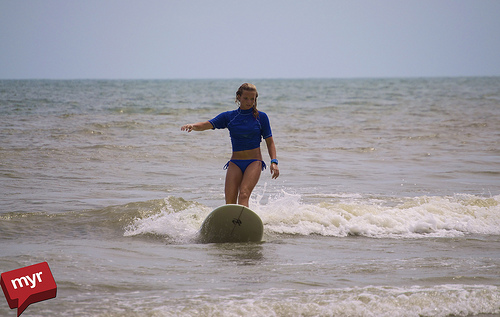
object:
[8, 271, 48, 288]
letter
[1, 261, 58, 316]
box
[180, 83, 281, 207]
surfer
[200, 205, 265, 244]
surfboard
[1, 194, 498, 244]
wave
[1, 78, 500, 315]
water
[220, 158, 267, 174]
bikini bottom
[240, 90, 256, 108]
face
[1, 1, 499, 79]
sky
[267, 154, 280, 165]
wrist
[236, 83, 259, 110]
head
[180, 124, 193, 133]
hand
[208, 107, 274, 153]
shirt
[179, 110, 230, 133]
arm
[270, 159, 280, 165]
bracelet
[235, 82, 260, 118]
hair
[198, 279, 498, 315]
bubbles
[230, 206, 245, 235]
string